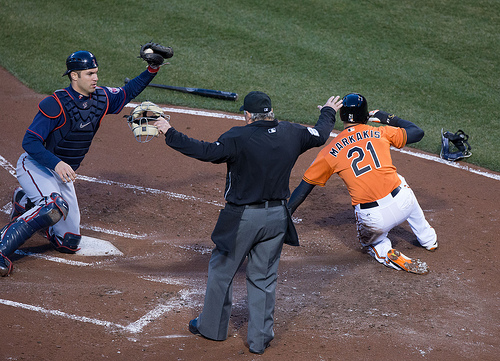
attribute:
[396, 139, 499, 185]
line — white 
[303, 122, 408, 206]
jersey — orange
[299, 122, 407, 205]
shirt — orange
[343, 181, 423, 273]
pants — White 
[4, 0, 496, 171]
grass — green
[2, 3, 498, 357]
field — green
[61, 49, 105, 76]
helmet — black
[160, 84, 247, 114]
baseballbat — metal, black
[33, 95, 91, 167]
uniform — blue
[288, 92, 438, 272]
player — sliding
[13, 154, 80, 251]
pants — gray, red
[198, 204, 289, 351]
pants — dark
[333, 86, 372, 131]
helmet — black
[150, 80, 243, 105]
bat — long, black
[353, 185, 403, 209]
belt — black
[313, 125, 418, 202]
shirt — black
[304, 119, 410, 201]
jersey — orange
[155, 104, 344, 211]
shirt — black